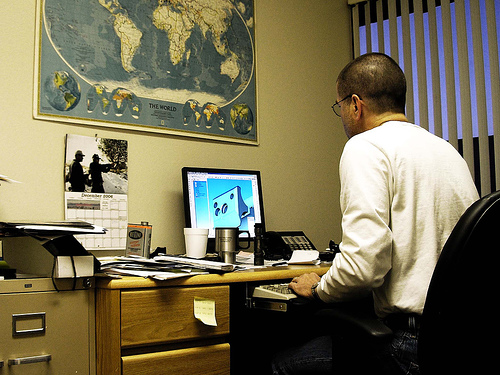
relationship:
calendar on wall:
[61, 130, 130, 253] [2, 0, 357, 256]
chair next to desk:
[415, 188, 499, 374] [97, 249, 344, 374]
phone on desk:
[268, 229, 319, 261] [87, 255, 362, 374]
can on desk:
[127, 219, 178, 250] [102, 247, 277, 374]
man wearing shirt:
[257, 50, 482, 374] [320, 120, 480, 317]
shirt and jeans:
[320, 120, 480, 317] [246, 313, 421, 373]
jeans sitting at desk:
[246, 313, 421, 373] [95, 263, 332, 372]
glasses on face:
[325, 95, 360, 118] [329, 80, 361, 139]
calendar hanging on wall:
[61, 130, 130, 253] [2, 0, 357, 256]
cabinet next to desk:
[1, 277, 98, 374] [95, 263, 332, 372]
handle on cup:
[236, 230, 251, 250] [183, 226, 209, 258]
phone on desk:
[261, 221, 319, 267] [87, 255, 362, 374]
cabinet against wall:
[1, 277, 98, 374] [2, 0, 357, 256]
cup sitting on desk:
[182, 217, 212, 260] [116, 277, 258, 361]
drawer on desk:
[119, 286, 231, 346] [97, 249, 344, 374]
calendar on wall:
[61, 130, 130, 253] [13, 39, 330, 224]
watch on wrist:
[308, 280, 324, 305] [309, 275, 334, 300]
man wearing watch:
[257, 50, 482, 374] [308, 280, 324, 305]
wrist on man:
[309, 275, 334, 300] [257, 50, 482, 374]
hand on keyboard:
[291, 272, 319, 292] [252, 281, 320, 300]